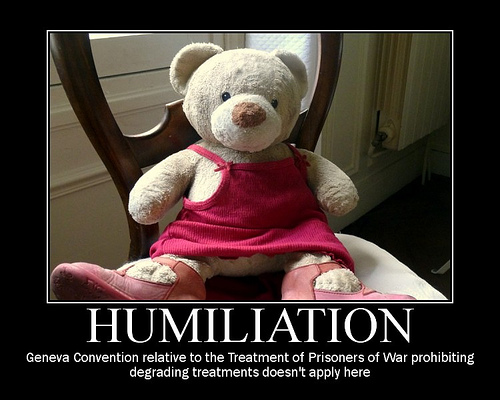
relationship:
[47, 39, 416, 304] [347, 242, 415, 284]
bear sitting on chair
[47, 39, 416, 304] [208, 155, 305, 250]
bear has dress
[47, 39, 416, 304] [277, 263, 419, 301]
bear has shoe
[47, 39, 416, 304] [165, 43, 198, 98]
bear has ear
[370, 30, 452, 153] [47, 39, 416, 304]
radiator on right side of bear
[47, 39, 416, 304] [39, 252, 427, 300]
bear wearing shoes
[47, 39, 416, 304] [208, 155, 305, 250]
bear wearing dress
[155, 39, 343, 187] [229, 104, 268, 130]
bear has nose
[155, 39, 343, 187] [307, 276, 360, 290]
bear has foot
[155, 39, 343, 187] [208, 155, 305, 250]
bear in a dress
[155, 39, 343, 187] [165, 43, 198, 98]
bear has ear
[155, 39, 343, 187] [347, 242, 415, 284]
bear on a chair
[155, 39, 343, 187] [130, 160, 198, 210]
bear has arm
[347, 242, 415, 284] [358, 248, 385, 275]
chair has seat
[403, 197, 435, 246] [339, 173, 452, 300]
floor on floor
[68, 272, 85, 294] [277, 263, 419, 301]
sole of shoe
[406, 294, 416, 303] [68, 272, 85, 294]
tip of sole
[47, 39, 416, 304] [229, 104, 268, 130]
bear has nose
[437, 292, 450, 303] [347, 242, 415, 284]
edge of chair